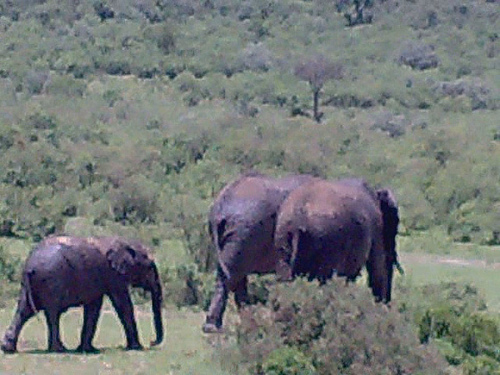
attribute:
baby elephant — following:
[2, 235, 163, 351]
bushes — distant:
[6, 10, 497, 348]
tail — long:
[207, 216, 234, 281]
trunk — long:
[144, 280, 165, 347]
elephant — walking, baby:
[0, 228, 170, 360]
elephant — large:
[204, 175, 306, 317]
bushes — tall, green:
[3, 1, 496, 162]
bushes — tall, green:
[36, 44, 492, 216]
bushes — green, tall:
[1, 2, 498, 310]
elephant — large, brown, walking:
[275, 176, 404, 307]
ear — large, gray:
[105, 231, 160, 279]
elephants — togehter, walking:
[1, 169, 401, 351]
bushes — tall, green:
[355, 40, 463, 128]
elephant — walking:
[202, 167, 320, 335]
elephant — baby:
[28, 229, 183, 349]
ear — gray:
[105, 240, 135, 276]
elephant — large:
[272, 165, 419, 321]